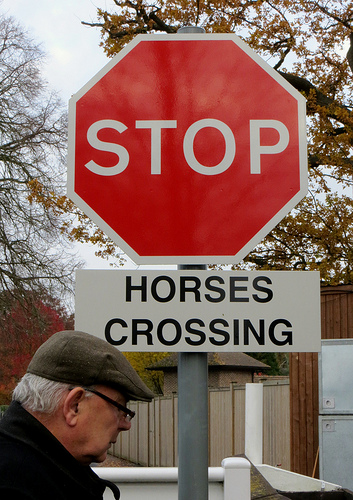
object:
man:
[0, 329, 156, 500]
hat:
[25, 328, 158, 402]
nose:
[119, 415, 130, 432]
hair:
[12, 372, 97, 410]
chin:
[96, 446, 108, 462]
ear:
[62, 385, 85, 426]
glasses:
[68, 386, 135, 424]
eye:
[111, 404, 126, 417]